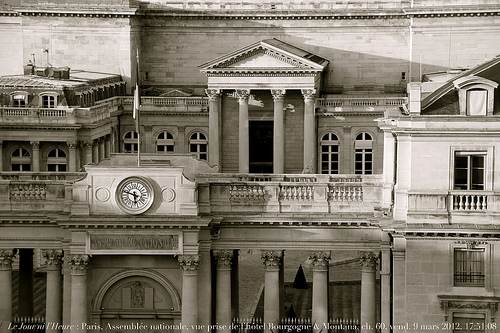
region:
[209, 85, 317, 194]
the columns on the upper deck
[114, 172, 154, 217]
the clock on the building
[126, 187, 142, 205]
the black hands of the clock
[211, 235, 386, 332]
the columns holding up the balcony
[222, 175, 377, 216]
the conret guradrail on the patio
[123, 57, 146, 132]
the flag on the building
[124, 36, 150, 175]
the flag pole above the clock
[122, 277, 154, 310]
a carving above the doorway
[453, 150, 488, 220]
the window on the building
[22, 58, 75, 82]
the buckets on the roof of the building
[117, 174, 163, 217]
white clock on building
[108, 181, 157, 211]
black hands on clock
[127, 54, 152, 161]
flag pole above clock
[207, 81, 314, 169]
grey pillars on building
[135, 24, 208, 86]
light brick on building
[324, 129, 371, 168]
arched windows on building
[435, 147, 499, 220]
rectangular windows on right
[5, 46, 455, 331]
building has grey front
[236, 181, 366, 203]
grey rails on upper level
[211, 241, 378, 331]
large columns on lower floor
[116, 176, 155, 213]
Clock on the top of the building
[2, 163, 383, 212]
Balcony roof on the top of the building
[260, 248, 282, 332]
Column support of the building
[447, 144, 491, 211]
Window on the top floor of the building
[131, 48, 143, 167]
Flag pole on the top of the building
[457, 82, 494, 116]
Small attic window on the top of the building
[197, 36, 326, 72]
Triangular roof of the building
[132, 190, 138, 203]
Hour hand of the clock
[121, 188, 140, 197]
minute hand of the clock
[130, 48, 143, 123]
flag hanging on the flag pole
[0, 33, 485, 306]
large building with several rooms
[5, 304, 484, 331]
lettering on bottom on image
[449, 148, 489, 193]
windows on the building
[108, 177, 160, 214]
clock on the building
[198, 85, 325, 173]
columns on top level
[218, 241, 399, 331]
columns on bottom level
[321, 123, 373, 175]
windows with arched tops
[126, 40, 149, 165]
flag on top of building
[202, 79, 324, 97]
decoration on top of column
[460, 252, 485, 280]
curtain to the window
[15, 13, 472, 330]
A beautiful white mansion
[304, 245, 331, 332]
A beautiful white mansion's pillar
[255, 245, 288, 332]
A beautiful white mansion's pillar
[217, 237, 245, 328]
A beautiful white mansion's pillar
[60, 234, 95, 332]
A beautiful white mansion's pillar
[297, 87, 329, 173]
A beautiful white mansion's pillar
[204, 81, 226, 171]
A beautiful white mansion's pillar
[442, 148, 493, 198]
A beautiful white mansion's window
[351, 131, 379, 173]
A beautiful white mansion's window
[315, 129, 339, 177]
A beautiful white mansion's window